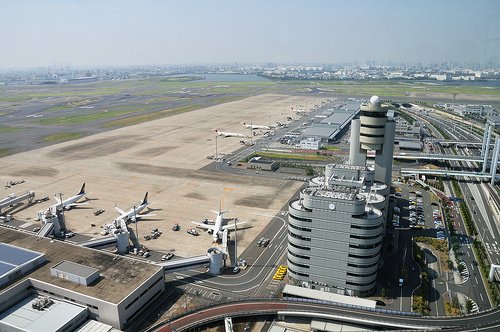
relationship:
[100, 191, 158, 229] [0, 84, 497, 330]
airplane at airport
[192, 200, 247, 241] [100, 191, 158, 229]
airplane next to airplane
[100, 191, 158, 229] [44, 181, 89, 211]
airplane next to airplane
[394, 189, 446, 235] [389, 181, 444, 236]
cars parked in parking lot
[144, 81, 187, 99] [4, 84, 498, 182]
grass on ground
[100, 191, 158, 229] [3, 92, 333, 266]
airplane parked on runway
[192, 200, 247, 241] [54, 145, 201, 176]
airplane parked on runway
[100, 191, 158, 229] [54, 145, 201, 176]
airplane parked on runway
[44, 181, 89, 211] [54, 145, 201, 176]
airplane parked on runway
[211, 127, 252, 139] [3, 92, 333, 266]
airplane parked on runway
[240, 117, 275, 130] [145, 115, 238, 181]
airplane parked on runway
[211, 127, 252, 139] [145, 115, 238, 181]
airplane parked on runway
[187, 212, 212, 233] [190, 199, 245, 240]
wing on side of airplane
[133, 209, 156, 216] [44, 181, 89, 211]
wing on side of airplane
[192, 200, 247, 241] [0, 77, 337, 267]
airplane at airport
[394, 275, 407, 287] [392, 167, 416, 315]
truck on road